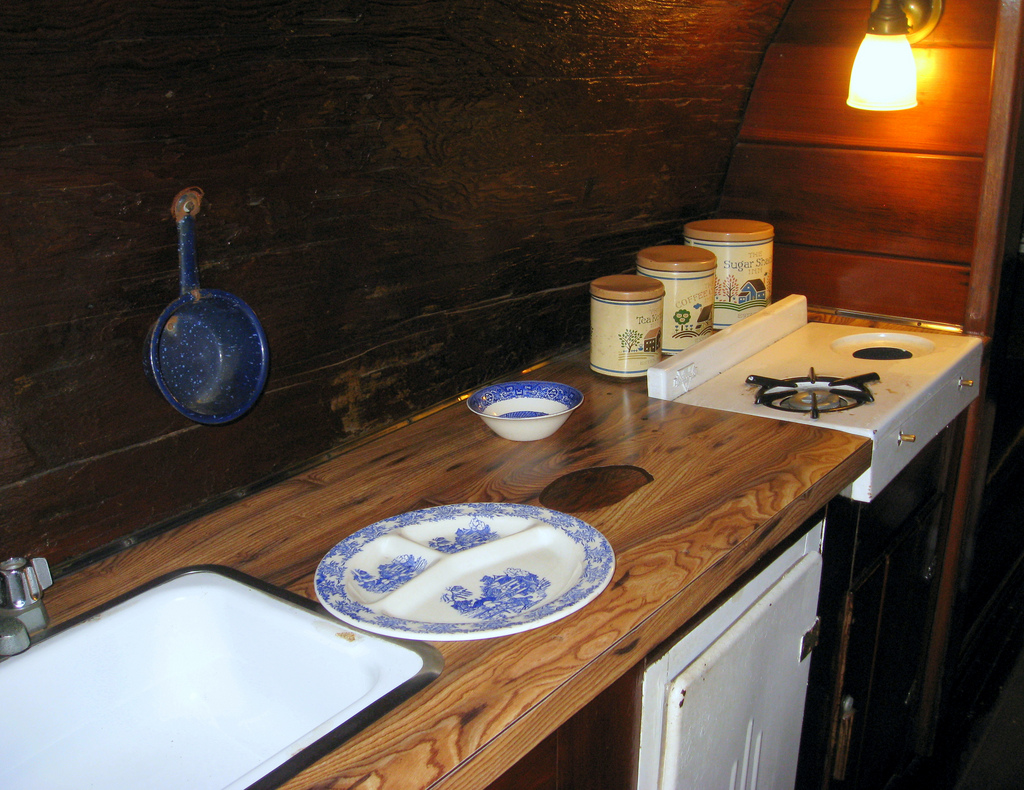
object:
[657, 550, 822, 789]
door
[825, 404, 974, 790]
cabinet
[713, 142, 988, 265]
panel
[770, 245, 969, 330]
panel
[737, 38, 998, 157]
panel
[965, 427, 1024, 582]
panel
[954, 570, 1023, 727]
panel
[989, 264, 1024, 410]
panel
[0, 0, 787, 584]
panel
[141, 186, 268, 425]
pot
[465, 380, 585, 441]
bowl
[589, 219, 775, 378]
canisters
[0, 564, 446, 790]
sink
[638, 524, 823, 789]
refrigerator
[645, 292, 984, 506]
stove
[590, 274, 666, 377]
canister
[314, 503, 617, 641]
dishes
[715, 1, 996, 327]
wood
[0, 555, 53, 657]
faucet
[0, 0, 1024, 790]
kitchen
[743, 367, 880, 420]
stove top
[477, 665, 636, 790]
counter